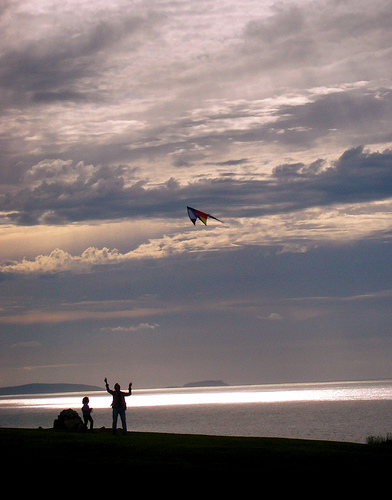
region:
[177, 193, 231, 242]
colorful kite in the sky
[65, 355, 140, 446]
two people flying a kite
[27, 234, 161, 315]
large white and grey clouds covering sky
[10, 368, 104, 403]
land in the distance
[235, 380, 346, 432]
calm ocean water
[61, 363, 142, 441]
adult and child flying a kite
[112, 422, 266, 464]
bright green grass on a hill over ocean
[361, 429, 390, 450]
small patch of tall grass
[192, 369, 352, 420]
sunlight shining on ocean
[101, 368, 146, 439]
person with hands in the air to fly kite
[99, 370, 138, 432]
silhouette of a man with his arms up in the air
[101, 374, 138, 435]
silhouette of a man standing at the edge of the ocean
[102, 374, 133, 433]
silhouette of a man standing with his young daughter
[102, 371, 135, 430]
silhouette of a man flying a kite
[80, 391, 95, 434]
silhouette of a young child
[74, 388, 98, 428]
silhouette of a child standing with her father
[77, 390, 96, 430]
silhouette of a child watching a flying kite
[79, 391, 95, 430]
silhouette of a child standing at the edge of the ocean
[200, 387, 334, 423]
ocean water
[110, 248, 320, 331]
cloudy sky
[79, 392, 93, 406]
the head of a child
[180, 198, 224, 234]
a kite in the sky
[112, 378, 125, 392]
the head of a person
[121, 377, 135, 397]
the arm of the person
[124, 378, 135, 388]
the hand of a person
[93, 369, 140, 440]
a person on the beach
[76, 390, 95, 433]
a child on the beach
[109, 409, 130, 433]
the legs of a person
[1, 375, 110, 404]
a hill in the distance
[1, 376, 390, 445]
a large body of water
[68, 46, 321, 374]
Picture is taken outside.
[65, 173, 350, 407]
The sun is behind the clouds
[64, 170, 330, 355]
The clouds are light grey in color.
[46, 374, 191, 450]
Two people on sand.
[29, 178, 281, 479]
The people are flying a kite.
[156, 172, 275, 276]
The kite is colorful.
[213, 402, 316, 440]
The water is calm.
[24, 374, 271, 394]
Mountains are in the background.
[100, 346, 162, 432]
The person is holding the arms in the air.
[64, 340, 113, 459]
A boy is holding the kite.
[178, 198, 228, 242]
Multi-colored kite up in the air.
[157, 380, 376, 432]
Ocean with steady white caps.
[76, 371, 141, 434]
Silhouette of two people standing on a beach.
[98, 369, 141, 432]
Silhouette of a man flying a kite.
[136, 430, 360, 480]
Beach and shore line darkened from cloud cover.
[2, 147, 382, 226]
Storm clouds suggest a future storm.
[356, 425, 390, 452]
Waterside vegetation.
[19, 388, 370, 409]
The sun peaking in through a break in the overcast.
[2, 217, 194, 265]
The sun's reflections off of higher clouds.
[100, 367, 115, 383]
Kite handle with spare string.